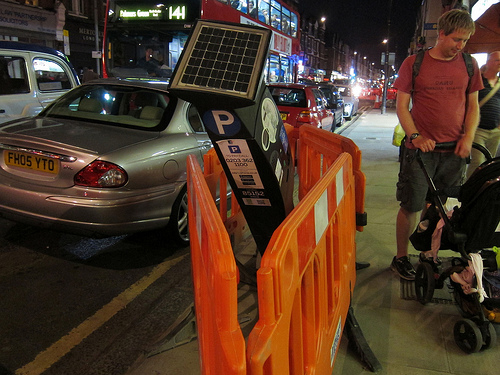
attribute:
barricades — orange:
[159, 117, 381, 374]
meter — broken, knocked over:
[148, 17, 295, 244]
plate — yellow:
[5, 149, 61, 176]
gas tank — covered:
[158, 152, 186, 185]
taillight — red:
[72, 156, 127, 191]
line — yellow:
[0, 253, 190, 375]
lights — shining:
[329, 72, 375, 94]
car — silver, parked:
[14, 75, 205, 257]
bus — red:
[104, 0, 304, 108]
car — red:
[260, 77, 346, 149]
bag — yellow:
[396, 116, 408, 149]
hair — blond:
[436, 10, 470, 43]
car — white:
[0, 52, 70, 116]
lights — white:
[101, 170, 125, 193]